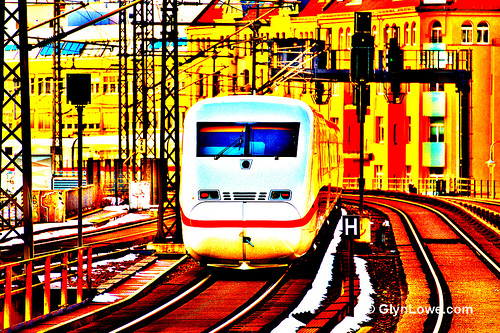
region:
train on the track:
[182, 96, 337, 252]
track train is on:
[179, 288, 249, 328]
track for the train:
[386, 207, 458, 241]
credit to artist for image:
[363, 279, 485, 329]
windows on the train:
[202, 124, 287, 155]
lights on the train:
[202, 183, 290, 202]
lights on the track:
[308, 23, 415, 113]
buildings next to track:
[185, 5, 498, 195]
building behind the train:
[6, 33, 181, 155]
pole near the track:
[62, 66, 107, 258]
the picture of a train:
[2, 0, 498, 327]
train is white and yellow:
[163, 87, 353, 274]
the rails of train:
[87, 270, 291, 331]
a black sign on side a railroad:
[61, 64, 96, 244]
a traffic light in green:
[382, 31, 409, 87]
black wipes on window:
[187, 117, 298, 162]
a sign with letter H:
[334, 202, 366, 321]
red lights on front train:
[191, 181, 296, 201]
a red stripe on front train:
[170, 196, 322, 233]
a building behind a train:
[151, 2, 494, 281]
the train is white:
[182, 101, 317, 284]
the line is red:
[184, 207, 307, 242]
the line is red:
[194, 209, 281, 232]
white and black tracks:
[108, 255, 312, 330]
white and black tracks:
[355, 190, 497, 330]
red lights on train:
[195, 190, 220, 202]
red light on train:
[271, 187, 291, 199]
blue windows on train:
[193, 116, 241, 166]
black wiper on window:
[212, 131, 243, 161]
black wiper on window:
[272, 133, 299, 158]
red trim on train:
[180, 211, 318, 226]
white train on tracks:
[182, 98, 337, 273]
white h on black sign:
[343, 215, 358, 239]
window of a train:
[203, 123, 218, 155]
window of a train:
[222, 122, 236, 159]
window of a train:
[249, 132, 269, 153]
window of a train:
[272, 121, 296, 155]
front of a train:
[169, 193, 301, 263]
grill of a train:
[213, 183, 275, 207]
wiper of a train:
[212, 106, 254, 166]